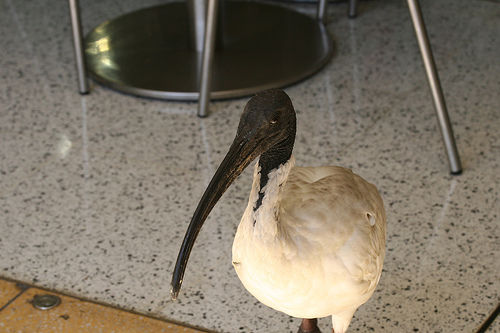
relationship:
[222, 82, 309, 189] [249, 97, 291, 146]
head has side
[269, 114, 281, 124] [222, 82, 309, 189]
eye on head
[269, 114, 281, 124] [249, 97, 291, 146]
eye on side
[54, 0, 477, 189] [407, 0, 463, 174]
chair has chair leg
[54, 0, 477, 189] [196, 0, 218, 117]
chair has chair leg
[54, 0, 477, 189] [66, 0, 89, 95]
chair has chair leg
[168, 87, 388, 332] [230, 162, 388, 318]
bird has body